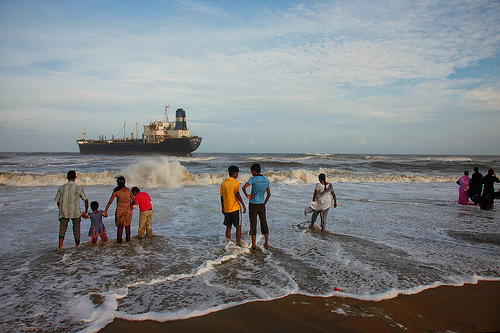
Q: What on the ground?
A: Sand.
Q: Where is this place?
A: Beach.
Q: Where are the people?
A: In the water.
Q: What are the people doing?
A: Looking at a big boat.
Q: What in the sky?
A: Clouds.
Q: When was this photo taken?
A: During the day.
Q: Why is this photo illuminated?
A: Sunlight.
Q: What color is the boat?
A: Black.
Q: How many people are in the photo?
A: 10.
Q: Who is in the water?
A: The boat.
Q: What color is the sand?
A: Brown.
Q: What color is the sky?
A: Blue.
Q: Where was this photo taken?
A: On a beach.